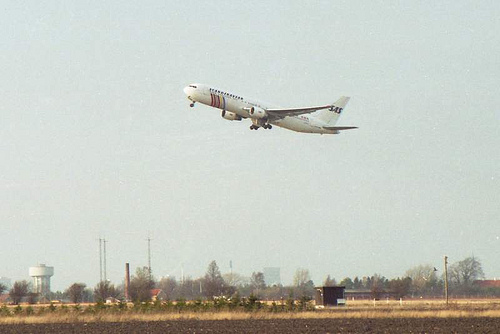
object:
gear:
[189, 97, 200, 108]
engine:
[243, 104, 267, 124]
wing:
[261, 96, 331, 127]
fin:
[318, 95, 358, 125]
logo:
[326, 103, 346, 120]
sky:
[7, 8, 493, 265]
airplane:
[179, 67, 371, 142]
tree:
[9, 277, 34, 304]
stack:
[119, 262, 137, 310]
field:
[0, 299, 492, 323]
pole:
[442, 250, 453, 302]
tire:
[249, 122, 258, 132]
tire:
[260, 117, 273, 129]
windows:
[205, 81, 245, 104]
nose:
[180, 81, 205, 106]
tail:
[319, 91, 353, 131]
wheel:
[257, 114, 276, 133]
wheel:
[248, 123, 260, 132]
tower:
[24, 251, 75, 301]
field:
[49, 268, 123, 313]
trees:
[62, 279, 152, 330]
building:
[311, 279, 373, 320]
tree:
[416, 245, 479, 315]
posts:
[357, 278, 399, 314]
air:
[84, 82, 187, 227]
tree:
[181, 250, 241, 307]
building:
[313, 278, 351, 312]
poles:
[89, 240, 119, 298]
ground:
[87, 312, 160, 331]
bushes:
[85, 278, 232, 309]